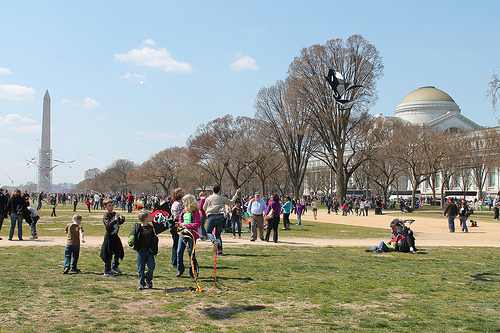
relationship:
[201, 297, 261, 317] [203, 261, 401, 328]
shadow on grass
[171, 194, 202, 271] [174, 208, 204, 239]
girl wearing jacket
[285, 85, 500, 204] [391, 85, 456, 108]
building has dome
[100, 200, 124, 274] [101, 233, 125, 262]
kid has jacket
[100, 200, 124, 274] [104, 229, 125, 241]
kid has waist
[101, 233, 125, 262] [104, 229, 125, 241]
jacket around waist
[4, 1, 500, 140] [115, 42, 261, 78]
sky has clouds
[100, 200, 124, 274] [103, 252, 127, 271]
kid has jeans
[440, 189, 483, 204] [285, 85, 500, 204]
bus near building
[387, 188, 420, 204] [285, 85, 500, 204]
bus near building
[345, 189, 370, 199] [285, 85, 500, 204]
bus near building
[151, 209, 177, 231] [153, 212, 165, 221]
kite has skull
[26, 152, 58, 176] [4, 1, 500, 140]
kite in sky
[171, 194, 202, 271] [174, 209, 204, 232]
girl has jacket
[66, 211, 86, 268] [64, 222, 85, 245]
kid has shirt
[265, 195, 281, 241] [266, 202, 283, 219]
lady has shirt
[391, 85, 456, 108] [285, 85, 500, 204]
dome on building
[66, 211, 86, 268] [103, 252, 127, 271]
kid has jeans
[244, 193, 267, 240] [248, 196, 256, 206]
man has bag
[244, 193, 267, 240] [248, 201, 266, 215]
man wearing shirt